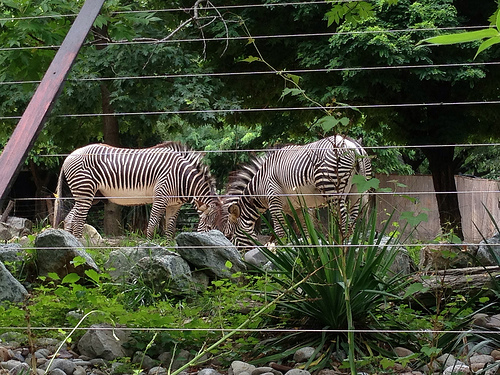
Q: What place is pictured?
A: It is a zoo.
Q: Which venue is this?
A: This is a zoo.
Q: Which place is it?
A: It is a zoo.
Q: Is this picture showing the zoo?
A: Yes, it is showing the zoo.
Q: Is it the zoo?
A: Yes, it is the zoo.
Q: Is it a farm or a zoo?
A: It is a zoo.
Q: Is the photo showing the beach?
A: No, the picture is showing the zoo.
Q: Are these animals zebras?
A: Yes, all the animals are zebras.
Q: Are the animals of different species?
A: No, all the animals are zebras.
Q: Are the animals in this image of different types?
A: No, all the animals are zebras.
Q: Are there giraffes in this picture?
A: No, there are no giraffes.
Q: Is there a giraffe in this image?
A: No, there are no giraffes.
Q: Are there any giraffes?
A: No, there are no giraffes.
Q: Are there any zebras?
A: Yes, there is a zebra.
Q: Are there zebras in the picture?
A: Yes, there is a zebra.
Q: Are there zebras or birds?
A: Yes, there is a zebra.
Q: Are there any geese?
A: No, there are no geese.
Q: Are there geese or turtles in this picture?
A: No, there are no geese or turtles.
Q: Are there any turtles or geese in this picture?
A: No, there are no geese or turtles.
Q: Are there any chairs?
A: No, there are no chairs.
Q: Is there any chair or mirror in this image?
A: No, there are no chairs or mirrors.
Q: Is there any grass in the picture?
A: Yes, there is grass.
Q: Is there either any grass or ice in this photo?
A: Yes, there is grass.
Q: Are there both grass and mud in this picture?
A: No, there is grass but no mud.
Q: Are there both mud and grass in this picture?
A: No, there is grass but no mud.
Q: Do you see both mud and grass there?
A: No, there is grass but no mud.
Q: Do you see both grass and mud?
A: No, there is grass but no mud.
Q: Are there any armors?
A: No, there are no armors.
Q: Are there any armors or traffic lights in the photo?
A: No, there are no armors or traffic lights.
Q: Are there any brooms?
A: No, there are no brooms.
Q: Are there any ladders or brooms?
A: No, there are no brooms or ladders.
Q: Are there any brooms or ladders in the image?
A: No, there are no brooms or ladders.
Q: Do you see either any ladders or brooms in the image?
A: No, there are no brooms or ladders.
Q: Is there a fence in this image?
A: Yes, there is a fence.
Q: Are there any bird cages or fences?
A: Yes, there is a fence.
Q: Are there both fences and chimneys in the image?
A: No, there is a fence but no chimneys.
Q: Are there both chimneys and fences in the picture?
A: No, there is a fence but no chimneys.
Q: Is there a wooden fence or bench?
A: Yes, there is a wood fence.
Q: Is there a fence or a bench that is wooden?
A: Yes, the fence is wooden.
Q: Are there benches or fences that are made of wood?
A: Yes, the fence is made of wood.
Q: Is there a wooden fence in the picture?
A: Yes, there is a wood fence.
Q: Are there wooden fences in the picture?
A: Yes, there is a wood fence.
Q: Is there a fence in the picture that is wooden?
A: Yes, there is a fence that is wooden.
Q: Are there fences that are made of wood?
A: Yes, there is a fence that is made of wood.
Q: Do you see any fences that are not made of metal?
A: Yes, there is a fence that is made of wood.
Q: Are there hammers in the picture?
A: No, there are no hammers.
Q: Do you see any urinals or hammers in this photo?
A: No, there are no hammers or urinals.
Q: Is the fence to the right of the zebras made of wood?
A: Yes, the fence is made of wood.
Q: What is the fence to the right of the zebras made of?
A: The fence is made of wood.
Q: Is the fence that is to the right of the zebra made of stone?
A: No, the fence is made of wood.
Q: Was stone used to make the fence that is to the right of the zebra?
A: No, the fence is made of wood.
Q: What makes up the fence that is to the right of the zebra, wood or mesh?
A: The fence is made of wood.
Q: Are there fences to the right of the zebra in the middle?
A: Yes, there is a fence to the right of the zebra.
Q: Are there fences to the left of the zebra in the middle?
A: No, the fence is to the right of the zebra.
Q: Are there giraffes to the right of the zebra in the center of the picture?
A: No, there is a fence to the right of the zebra.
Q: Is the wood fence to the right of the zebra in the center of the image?
A: Yes, the fence is to the right of the zebra.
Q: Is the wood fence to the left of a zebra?
A: No, the fence is to the right of a zebra.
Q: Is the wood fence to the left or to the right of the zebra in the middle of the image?
A: The fence is to the right of the zebra.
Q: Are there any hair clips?
A: No, there are no hair clips.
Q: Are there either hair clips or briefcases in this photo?
A: No, there are no hair clips or briefcases.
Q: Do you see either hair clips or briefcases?
A: No, there are no hair clips or briefcases.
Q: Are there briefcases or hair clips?
A: No, there are no hair clips or briefcases.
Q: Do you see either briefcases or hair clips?
A: No, there are no hair clips or briefcases.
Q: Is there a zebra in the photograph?
A: Yes, there is a zebra.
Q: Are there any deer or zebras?
A: Yes, there is a zebra.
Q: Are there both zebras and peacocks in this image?
A: No, there is a zebra but no peacocks.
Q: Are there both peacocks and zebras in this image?
A: No, there is a zebra but no peacocks.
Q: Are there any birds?
A: No, there are no birds.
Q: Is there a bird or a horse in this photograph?
A: No, there are no birds or horses.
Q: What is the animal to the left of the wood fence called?
A: The animal is a zebra.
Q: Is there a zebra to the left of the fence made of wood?
A: Yes, there is a zebra to the left of the fence.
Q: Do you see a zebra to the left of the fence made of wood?
A: Yes, there is a zebra to the left of the fence.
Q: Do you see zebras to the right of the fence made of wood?
A: No, the zebra is to the left of the fence.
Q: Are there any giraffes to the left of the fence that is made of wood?
A: No, there is a zebra to the left of the fence.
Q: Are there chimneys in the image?
A: No, there are no chimneys.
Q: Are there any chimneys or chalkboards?
A: No, there are no chimneys or chalkboards.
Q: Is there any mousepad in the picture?
A: No, there are no mouse pads.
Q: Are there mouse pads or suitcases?
A: No, there are no mouse pads or suitcases.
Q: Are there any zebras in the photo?
A: Yes, there are zebras.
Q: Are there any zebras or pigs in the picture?
A: Yes, there are zebras.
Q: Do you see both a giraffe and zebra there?
A: No, there are zebras but no giraffes.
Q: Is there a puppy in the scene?
A: No, there are no puppys.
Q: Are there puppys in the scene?
A: No, there are no puppys.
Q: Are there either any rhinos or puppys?
A: No, there are no puppys or rhinos.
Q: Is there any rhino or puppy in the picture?
A: No, there are no puppys or rhinos.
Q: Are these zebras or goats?
A: These are zebras.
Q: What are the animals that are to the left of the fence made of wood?
A: The animals are zebras.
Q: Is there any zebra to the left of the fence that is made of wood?
A: Yes, there are zebras to the left of the fence.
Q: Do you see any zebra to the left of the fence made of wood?
A: Yes, there are zebras to the left of the fence.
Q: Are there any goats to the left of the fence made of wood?
A: No, there are zebras to the left of the fence.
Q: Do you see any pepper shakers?
A: No, there are no pepper shakers.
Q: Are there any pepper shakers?
A: No, there are no pepper shakers.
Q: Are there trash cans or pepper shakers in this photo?
A: No, there are no pepper shakers or trash cans.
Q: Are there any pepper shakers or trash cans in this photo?
A: No, there are no pepper shakers or trash cans.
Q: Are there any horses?
A: No, there are no horses.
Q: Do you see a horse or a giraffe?
A: No, there are no horses or giraffes.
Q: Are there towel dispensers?
A: No, there are no towel dispensers.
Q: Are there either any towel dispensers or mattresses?
A: No, there are no towel dispensers or mattresses.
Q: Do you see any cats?
A: No, there are no cats.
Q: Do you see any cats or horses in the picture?
A: No, there are no cats or horses.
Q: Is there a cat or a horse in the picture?
A: No, there are no cats or horses.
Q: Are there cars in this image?
A: No, there are no cars.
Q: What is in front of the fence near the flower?
A: The trees are in front of the fence.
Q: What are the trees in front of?
A: The trees are in front of the fence.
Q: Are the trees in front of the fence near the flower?
A: Yes, the trees are in front of the fence.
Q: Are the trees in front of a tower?
A: No, the trees are in front of the fence.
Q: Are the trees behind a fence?
A: No, the trees are in front of a fence.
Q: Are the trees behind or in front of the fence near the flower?
A: The trees are in front of the fence.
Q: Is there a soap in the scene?
A: No, there are no soaps.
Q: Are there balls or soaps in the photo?
A: No, there are no soaps or balls.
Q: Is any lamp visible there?
A: No, there are no lamps.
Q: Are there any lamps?
A: No, there are no lamps.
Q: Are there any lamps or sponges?
A: No, there are no lamps or sponges.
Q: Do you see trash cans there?
A: No, there are no trash cans.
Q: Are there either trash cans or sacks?
A: No, there are no trash cans or sacks.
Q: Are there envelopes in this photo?
A: No, there are no envelopes.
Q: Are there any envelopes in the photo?
A: No, there are no envelopes.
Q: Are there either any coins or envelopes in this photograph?
A: No, there are no envelopes or coins.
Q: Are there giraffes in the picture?
A: No, there are no giraffes.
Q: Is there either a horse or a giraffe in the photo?
A: No, there are no giraffes or horses.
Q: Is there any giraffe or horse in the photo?
A: No, there are no giraffes or horses.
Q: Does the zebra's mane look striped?
A: Yes, the mane is striped.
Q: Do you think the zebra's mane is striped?
A: Yes, the mane is striped.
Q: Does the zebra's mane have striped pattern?
A: Yes, the mane is striped.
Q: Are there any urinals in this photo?
A: No, there are no urinals.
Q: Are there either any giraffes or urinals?
A: No, there are no urinals or giraffes.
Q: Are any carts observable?
A: No, there are no carts.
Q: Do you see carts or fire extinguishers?
A: No, there are no carts or fire extinguishers.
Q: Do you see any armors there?
A: No, there are no armors.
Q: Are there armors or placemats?
A: No, there are no armors or placemats.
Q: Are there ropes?
A: No, there are no ropes.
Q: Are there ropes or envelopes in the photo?
A: No, there are no ropes or envelopes.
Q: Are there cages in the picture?
A: No, there are no cages.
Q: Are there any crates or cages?
A: No, there are no cages or crates.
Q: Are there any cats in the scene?
A: No, there are no cats.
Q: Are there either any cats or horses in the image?
A: No, there are no cats or horses.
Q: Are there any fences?
A: Yes, there is a fence.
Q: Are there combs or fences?
A: Yes, there is a fence.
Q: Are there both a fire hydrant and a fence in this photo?
A: No, there is a fence but no fire hydrants.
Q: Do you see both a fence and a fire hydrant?
A: No, there is a fence but no fire hydrants.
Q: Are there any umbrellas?
A: No, there are no umbrellas.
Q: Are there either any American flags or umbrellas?
A: No, there are no umbrellas or American flags.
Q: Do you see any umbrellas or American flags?
A: No, there are no umbrellas or American flags.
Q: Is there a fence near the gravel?
A: Yes, there is a fence near the gravel.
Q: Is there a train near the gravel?
A: No, there is a fence near the gravel.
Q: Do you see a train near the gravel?
A: No, there is a fence near the gravel.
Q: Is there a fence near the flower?
A: Yes, there is a fence near the flower.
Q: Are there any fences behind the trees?
A: Yes, there is a fence behind the trees.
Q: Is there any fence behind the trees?
A: Yes, there is a fence behind the trees.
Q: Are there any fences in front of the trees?
A: No, the fence is behind the trees.